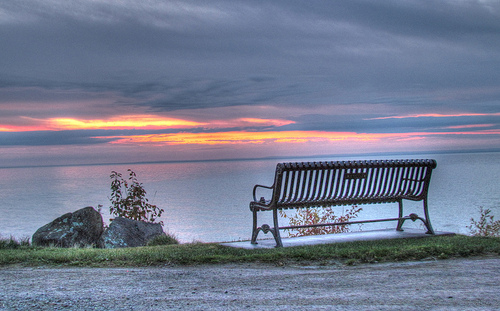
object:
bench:
[249, 158, 437, 248]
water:
[0, 151, 500, 243]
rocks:
[31, 206, 104, 249]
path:
[0, 256, 499, 310]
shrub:
[277, 205, 364, 239]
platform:
[220, 228, 455, 249]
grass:
[0, 236, 180, 266]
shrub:
[465, 205, 499, 238]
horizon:
[1, 148, 499, 169]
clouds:
[0, 0, 499, 146]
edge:
[0, 250, 499, 270]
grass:
[0, 236, 500, 267]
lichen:
[102, 223, 130, 249]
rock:
[97, 216, 166, 248]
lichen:
[44, 221, 94, 251]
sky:
[0, 2, 497, 142]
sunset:
[0, 112, 500, 149]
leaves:
[95, 168, 165, 227]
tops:
[108, 168, 138, 182]